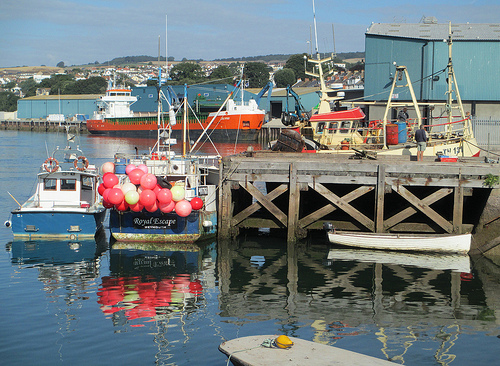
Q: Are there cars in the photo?
A: No, there are no cars.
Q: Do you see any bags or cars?
A: No, there are no cars or bags.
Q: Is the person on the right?
A: Yes, the person is on the right of the image.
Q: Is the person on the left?
A: No, the person is on the right of the image.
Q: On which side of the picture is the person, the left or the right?
A: The person is on the right of the image.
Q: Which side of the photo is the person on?
A: The person is on the right of the image.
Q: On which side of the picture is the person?
A: The person is on the right of the image.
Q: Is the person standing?
A: Yes, the person is standing.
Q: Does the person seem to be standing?
A: Yes, the person is standing.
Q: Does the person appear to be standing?
A: Yes, the person is standing.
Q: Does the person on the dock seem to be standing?
A: Yes, the person is standing.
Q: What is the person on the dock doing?
A: The person is standing.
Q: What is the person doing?
A: The person is standing.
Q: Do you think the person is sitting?
A: No, the person is standing.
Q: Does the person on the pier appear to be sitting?
A: No, the person is standing.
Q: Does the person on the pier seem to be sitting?
A: No, the person is standing.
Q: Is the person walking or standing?
A: The person is standing.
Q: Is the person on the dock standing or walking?
A: The person is standing.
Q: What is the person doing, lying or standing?
A: The person is standing.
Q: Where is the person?
A: The person is on the dock.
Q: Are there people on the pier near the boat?
A: Yes, there is a person on the dock.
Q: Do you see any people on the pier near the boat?
A: Yes, there is a person on the dock.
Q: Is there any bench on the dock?
A: No, there is a person on the dock.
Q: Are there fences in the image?
A: No, there are no fences.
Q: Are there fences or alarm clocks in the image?
A: No, there are no fences or alarm clocks.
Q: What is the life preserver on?
A: The life preserver is on the boat.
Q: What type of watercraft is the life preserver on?
A: The life preserver is on the boat.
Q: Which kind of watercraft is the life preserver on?
A: The life preserver is on the boat.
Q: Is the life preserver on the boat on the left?
A: Yes, the life preserver is on the boat.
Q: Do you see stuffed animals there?
A: No, there are no stuffed animals.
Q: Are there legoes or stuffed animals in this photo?
A: No, there are no stuffed animals or legoes.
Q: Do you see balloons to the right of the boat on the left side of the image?
A: Yes, there are balloons to the right of the boat.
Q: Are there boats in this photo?
A: Yes, there is a boat.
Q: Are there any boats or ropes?
A: Yes, there is a boat.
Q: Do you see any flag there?
A: No, there are no flags.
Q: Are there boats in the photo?
A: Yes, there is a boat.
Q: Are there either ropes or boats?
A: Yes, there is a boat.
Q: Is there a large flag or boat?
A: Yes, there is a large boat.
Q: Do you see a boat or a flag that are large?
A: Yes, the boat is large.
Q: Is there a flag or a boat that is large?
A: Yes, the boat is large.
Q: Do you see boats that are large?
A: Yes, there is a large boat.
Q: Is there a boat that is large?
A: Yes, there is a boat that is large.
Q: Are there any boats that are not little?
A: Yes, there is a large boat.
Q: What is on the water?
A: The boat is on the water.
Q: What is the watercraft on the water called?
A: The watercraft is a boat.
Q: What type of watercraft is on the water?
A: The watercraft is a boat.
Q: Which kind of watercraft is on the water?
A: The watercraft is a boat.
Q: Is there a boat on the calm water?
A: Yes, there is a boat on the water.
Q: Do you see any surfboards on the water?
A: No, there is a boat on the water.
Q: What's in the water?
A: The boat is in the water.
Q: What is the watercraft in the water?
A: The watercraft is a boat.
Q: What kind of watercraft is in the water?
A: The watercraft is a boat.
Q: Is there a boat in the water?
A: Yes, there is a boat in the water.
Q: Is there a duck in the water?
A: No, there is a boat in the water.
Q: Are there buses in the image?
A: No, there are no buses.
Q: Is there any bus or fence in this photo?
A: No, there are no buses or fences.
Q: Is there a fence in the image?
A: No, there are no fences.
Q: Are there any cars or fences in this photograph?
A: No, there are no fences or cars.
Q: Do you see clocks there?
A: No, there are no clocks.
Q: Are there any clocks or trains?
A: No, there are no clocks or trains.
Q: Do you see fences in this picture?
A: No, there are no fences.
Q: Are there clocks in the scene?
A: No, there are no clocks.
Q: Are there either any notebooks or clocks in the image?
A: No, there are no clocks or notebooks.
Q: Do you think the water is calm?
A: Yes, the water is calm.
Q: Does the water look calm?
A: Yes, the water is calm.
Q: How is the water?
A: The water is calm.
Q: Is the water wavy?
A: No, the water is calm.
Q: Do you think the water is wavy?
A: No, the water is calm.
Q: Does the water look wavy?
A: No, the water is calm.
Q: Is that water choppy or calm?
A: The water is calm.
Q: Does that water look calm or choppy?
A: The water is calm.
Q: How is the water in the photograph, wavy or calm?
A: The water is calm.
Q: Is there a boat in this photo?
A: Yes, there is a boat.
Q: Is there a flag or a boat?
A: Yes, there is a boat.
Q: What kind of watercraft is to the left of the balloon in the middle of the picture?
A: The watercraft is a boat.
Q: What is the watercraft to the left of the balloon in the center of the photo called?
A: The watercraft is a boat.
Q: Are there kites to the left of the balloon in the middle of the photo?
A: No, there is a boat to the left of the balloon.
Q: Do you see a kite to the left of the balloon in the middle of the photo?
A: No, there is a boat to the left of the balloon.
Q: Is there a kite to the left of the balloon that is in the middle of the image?
A: No, there is a boat to the left of the balloon.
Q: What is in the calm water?
A: The boat is in the water.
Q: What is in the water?
A: The boat is in the water.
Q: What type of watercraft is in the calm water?
A: The watercraft is a boat.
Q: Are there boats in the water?
A: Yes, there is a boat in the water.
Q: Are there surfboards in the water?
A: No, there is a boat in the water.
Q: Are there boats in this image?
A: Yes, there is a boat.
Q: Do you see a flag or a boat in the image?
A: Yes, there is a boat.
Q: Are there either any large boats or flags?
A: Yes, there is a large boat.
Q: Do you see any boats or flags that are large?
A: Yes, the boat is large.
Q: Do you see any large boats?
A: Yes, there is a large boat.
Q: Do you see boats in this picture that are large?
A: Yes, there is a boat that is large.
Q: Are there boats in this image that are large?
A: Yes, there is a boat that is large.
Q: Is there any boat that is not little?
A: Yes, there is a large boat.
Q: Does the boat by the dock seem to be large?
A: Yes, the boat is large.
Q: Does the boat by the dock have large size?
A: Yes, the boat is large.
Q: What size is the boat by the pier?
A: The boat is large.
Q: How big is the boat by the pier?
A: The boat is large.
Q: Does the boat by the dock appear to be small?
A: No, the boat is large.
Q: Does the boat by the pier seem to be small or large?
A: The boat is large.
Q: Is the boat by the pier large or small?
A: The boat is large.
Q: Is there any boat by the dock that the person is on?
A: Yes, there is a boat by the dock.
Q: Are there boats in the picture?
A: Yes, there is a boat.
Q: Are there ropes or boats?
A: Yes, there is a boat.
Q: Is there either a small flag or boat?
A: Yes, there is a small boat.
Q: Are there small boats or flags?
A: Yes, there is a small boat.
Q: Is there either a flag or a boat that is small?
A: Yes, the boat is small.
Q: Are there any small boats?
A: Yes, there is a small boat.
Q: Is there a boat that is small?
A: Yes, there is a boat that is small.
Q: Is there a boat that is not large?
A: Yes, there is a small boat.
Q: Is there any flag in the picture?
A: No, there are no flags.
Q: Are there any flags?
A: No, there are no flags.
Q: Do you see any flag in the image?
A: No, there are no flags.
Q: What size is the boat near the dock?
A: The boat is small.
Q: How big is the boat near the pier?
A: The boat is small.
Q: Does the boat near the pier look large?
A: No, the boat is small.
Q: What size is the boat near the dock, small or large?
A: The boat is small.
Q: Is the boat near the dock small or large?
A: The boat is small.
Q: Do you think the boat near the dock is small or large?
A: The boat is small.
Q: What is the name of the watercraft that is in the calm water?
A: The watercraft is a boat.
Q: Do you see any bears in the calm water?
A: No, there is a boat in the water.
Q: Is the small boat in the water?
A: Yes, the boat is in the water.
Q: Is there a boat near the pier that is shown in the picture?
A: Yes, there is a boat near the pier.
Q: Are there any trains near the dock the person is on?
A: No, there is a boat near the dock.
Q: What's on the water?
A: The boat is on the water.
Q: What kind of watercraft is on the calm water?
A: The watercraft is a boat.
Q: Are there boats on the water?
A: Yes, there is a boat on the water.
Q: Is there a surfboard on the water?
A: No, there is a boat on the water.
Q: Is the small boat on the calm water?
A: Yes, the boat is on the water.